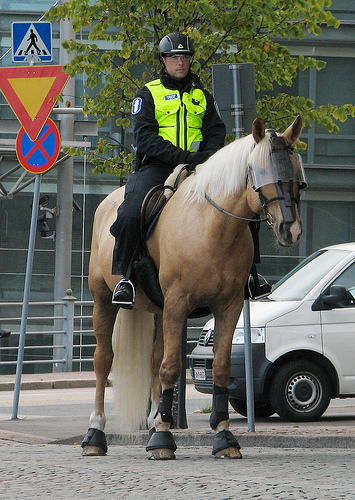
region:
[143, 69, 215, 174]
neon green safety vest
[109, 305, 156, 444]
long beige horse tail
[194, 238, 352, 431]
front half of white van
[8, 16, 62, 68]
pedestrian crosswalk sign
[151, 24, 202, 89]
man with helmet and glasses on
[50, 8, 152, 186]
tree with green leaves turning brown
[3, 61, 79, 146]
red and yellow yield sign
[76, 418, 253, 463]
black hoof covers on horse's feet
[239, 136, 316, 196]
clear visor on horse's eyes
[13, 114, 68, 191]
blue circle sign with red x in it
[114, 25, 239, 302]
man on tall horse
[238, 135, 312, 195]
horse has a shield on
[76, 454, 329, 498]
the road is made of brick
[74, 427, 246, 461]
the horse has hoof covers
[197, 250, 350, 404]
the van is white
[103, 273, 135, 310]
the mans foot is in a stirrup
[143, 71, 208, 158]
the man is wearing a yellow vest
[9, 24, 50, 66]
the sign has a pedestrian on it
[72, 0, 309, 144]
a tree behind the horse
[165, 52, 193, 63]
man has safety glasses on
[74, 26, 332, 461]
A man is on a horse.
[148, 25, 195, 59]
A man is wearing a black and white helmet.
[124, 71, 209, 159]
A man is wearing a lime-green colored vest.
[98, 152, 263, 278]
A man is wearing dark pants.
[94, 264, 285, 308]
A man is wearing dark shoes.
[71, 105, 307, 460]
A horse's colors are brown and white.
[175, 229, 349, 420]
A van is behind a horse.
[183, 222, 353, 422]
A van's colors are white and black.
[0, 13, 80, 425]
Three signs are behind a man on a horse.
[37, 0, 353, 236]
A tree is behind a man on a horse.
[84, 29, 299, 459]
police officer on brown horse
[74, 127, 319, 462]
large brown horse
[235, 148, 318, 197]
clear shield worn over horses eyes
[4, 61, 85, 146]
red and yellow triangle sign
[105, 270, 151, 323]
silver and black stirrups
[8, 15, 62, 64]
square sign indicating pedestrian crosswalk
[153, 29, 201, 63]
police officer wearing black helmet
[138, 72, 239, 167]
fluorescent yellow safety jacket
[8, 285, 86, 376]
metal silver fence on side of sidewalk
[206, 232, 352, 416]
white van parked on street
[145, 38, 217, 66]
Man wearing black helmet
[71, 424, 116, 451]
Black wraps around horse's feet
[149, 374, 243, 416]
Black wraps around horse's shin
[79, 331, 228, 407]
Horse is brown in color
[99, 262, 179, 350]
Man's feet in stirrups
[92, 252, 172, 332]
Man wearing black shoes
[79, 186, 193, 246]
Man wearing black pants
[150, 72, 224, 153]
Man wearing bright vest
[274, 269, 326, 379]
White van behind horse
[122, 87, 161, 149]
Blue patch on man's sleeve